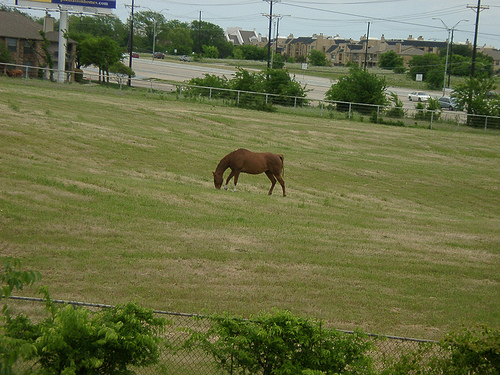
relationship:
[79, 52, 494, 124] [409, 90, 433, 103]
highway has cars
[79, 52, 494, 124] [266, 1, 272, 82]
highway has a power pole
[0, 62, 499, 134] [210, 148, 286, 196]
fence encloses animal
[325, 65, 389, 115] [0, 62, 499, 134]
bush in front of fence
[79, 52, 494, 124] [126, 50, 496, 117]
highway in distance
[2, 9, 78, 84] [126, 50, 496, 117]
buildings are in distance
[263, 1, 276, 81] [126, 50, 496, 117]
power pole in distance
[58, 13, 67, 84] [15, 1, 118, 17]
pole attached to billboard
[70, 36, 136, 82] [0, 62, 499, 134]
trees are facing fence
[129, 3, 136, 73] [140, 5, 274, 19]
telephone has hanging wires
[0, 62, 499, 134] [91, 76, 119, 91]
fence made of chain link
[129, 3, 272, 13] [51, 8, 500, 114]
lines are in background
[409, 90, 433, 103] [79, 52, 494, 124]
cars are on highway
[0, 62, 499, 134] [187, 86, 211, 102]
fence has wires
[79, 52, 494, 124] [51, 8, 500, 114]
highway in background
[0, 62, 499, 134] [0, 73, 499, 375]
fence surrounds field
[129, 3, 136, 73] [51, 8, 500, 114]
telephone in background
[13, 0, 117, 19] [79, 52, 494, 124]
sign on highway